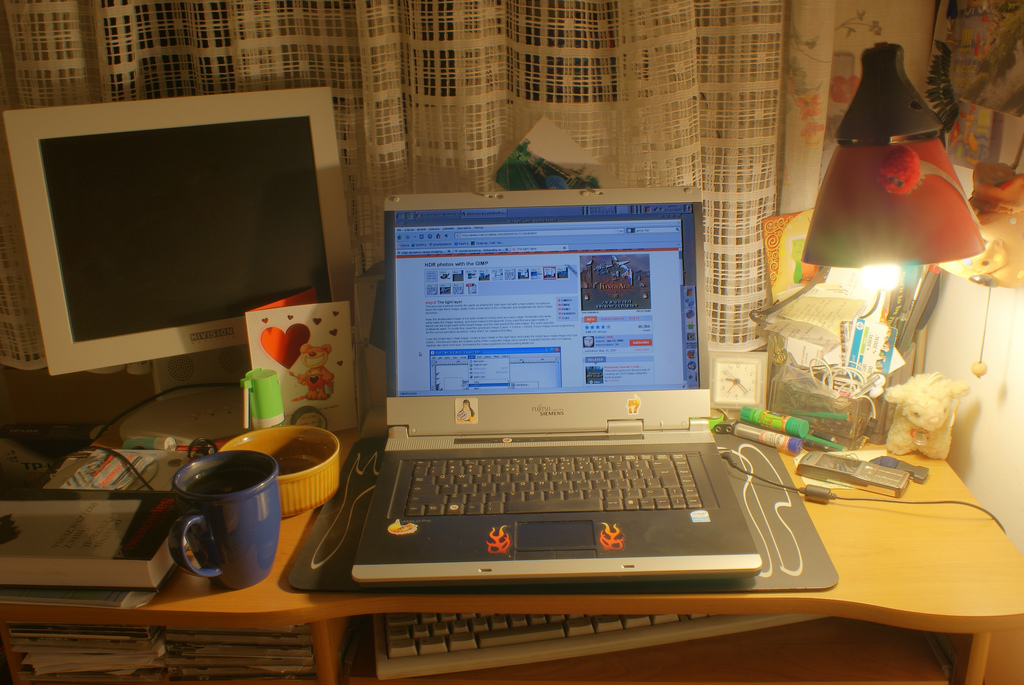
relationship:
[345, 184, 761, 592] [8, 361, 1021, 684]
laptop on desk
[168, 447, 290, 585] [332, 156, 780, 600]
mug next laptop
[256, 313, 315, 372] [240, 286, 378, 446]
heart on card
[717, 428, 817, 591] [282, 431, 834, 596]
pictures on play mat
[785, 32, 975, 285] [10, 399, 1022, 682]
lamp on desk